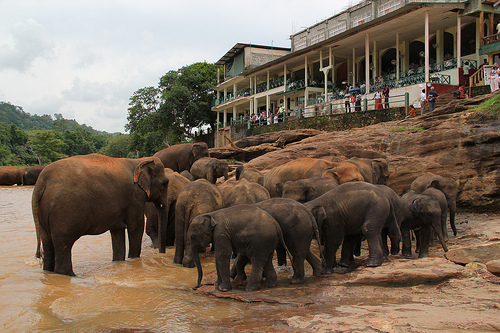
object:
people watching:
[224, 54, 499, 126]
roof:
[211, 41, 290, 69]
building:
[209, 0, 500, 147]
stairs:
[420, 63, 491, 109]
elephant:
[262, 158, 366, 197]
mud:
[0, 97, 499, 332]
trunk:
[190, 246, 205, 292]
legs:
[216, 245, 233, 284]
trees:
[124, 84, 185, 158]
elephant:
[189, 157, 229, 183]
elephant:
[1, 165, 26, 185]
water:
[2, 175, 216, 331]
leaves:
[10, 131, 27, 148]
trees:
[161, 62, 216, 130]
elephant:
[30, 153, 168, 277]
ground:
[337, 67, 411, 126]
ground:
[327, 207, 372, 237]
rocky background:
[250, 103, 499, 185]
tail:
[390, 199, 402, 242]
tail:
[275, 220, 293, 261]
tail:
[31, 171, 45, 259]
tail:
[180, 202, 190, 248]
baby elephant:
[182, 202, 287, 291]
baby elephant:
[255, 196, 323, 285]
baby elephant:
[296, 180, 404, 276]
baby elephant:
[401, 187, 451, 259]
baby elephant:
[412, 167, 463, 237]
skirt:
[373, 99, 382, 110]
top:
[374, 91, 382, 99]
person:
[371, 89, 382, 109]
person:
[354, 93, 361, 112]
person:
[427, 86, 438, 111]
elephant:
[174, 179, 223, 268]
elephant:
[149, 141, 208, 171]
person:
[344, 89, 350, 112]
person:
[352, 92, 356, 112]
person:
[457, 83, 467, 98]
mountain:
[0, 96, 133, 167]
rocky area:
[137, 107, 499, 333]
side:
[39, 164, 151, 231]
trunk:
[155, 197, 170, 253]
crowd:
[246, 72, 393, 110]